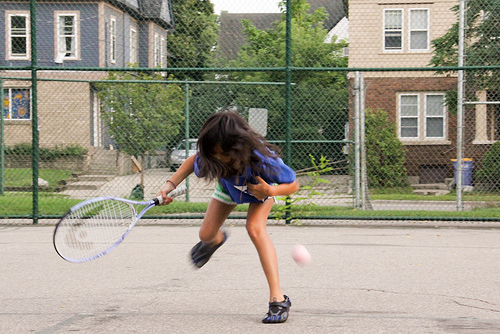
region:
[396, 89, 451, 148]
the window on the house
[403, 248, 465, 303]
the ground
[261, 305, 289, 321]
a shoe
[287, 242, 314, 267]
a ball in the air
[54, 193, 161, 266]
a tennis racket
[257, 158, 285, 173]
person is wearing a blue shirt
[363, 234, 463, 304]
the street is grey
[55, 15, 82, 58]
windows on the house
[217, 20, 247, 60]
the roof on the house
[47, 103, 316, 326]
a little girl playing tennis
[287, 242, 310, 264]
a tennis ball heading towards the girl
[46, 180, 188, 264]
a tennis racket in the girl's right hand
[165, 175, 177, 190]
a hair tie around the girl's right wrist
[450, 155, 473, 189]
a blue trash can in front of the house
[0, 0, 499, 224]
a green chain link fence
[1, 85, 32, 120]
a decorative curtain on the window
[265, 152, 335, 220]
a weed growing up from the tennis court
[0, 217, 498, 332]
asphalt pavement with lines and cracks on it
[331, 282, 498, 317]
a large crack in the pavement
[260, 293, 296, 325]
The left foot of the person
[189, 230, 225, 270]
The right foot of the person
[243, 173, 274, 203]
The left hand of the person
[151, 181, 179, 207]
The right hand of the person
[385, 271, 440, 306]
Part of the ground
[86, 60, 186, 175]
A green tree behind the fence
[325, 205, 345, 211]
Part of the green grass behind the fence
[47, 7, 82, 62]
A window on the house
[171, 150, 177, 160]
Part of the car behind the fence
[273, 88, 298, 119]
Part of the fence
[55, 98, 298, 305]
kid is holding a racket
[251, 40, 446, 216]
the fence is green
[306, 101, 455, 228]
the fence is green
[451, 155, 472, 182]
blue garbage can with yellow lid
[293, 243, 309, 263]
blurry pink ball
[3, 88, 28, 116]
blue fabric with suns in window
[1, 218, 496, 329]
concrete floor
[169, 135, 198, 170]
parked silver car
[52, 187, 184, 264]
light blue and black tennis racket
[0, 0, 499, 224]
green chain link fence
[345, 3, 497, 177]
brown and tan building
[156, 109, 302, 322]
girl with tennis racket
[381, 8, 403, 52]
open second story window